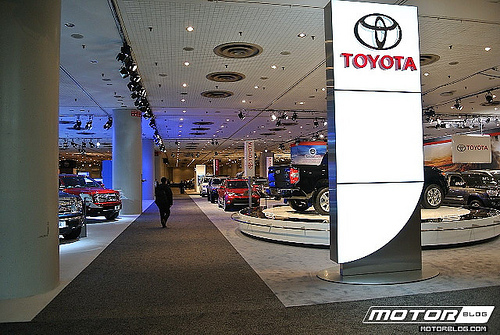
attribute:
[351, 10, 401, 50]
drawing — black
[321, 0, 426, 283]
sign — white, black, red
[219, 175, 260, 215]
car — red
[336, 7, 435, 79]
sign — Toyota, hanging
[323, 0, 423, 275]
large sign — bright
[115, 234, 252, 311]
carpet — gray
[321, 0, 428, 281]
board — white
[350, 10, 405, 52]
symbol — black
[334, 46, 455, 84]
words — red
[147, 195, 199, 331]
floor — rough, grey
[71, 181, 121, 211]
truck — red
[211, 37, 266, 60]
vent — gray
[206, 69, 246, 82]
vent — gray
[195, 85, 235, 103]
vent — gray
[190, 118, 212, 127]
vent — gray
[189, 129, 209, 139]
vent — gray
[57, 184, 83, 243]
truck — blue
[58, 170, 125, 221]
truck — red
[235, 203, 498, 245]
platform — round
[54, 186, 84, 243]
car — light blue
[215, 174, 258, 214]
suv — red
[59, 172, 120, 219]
suv — red